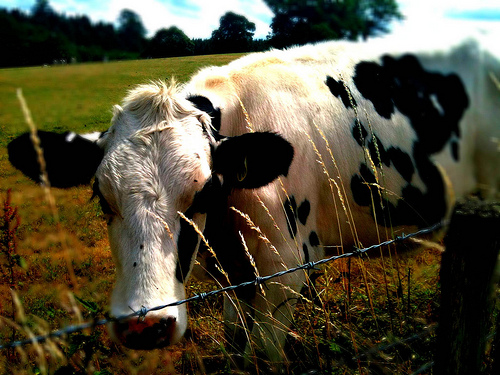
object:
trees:
[204, 11, 255, 54]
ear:
[210, 131, 295, 194]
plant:
[0, 189, 103, 375]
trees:
[0, 6, 31, 70]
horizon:
[0, 49, 233, 72]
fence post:
[437, 184, 496, 373]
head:
[5, 79, 295, 349]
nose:
[121, 314, 170, 347]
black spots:
[319, 52, 472, 229]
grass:
[4, 54, 211, 123]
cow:
[7, 13, 498, 363]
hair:
[116, 73, 199, 127]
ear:
[1, 127, 106, 189]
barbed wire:
[3, 218, 456, 350]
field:
[0, 41, 498, 375]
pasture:
[0, 49, 500, 375]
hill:
[0, 35, 251, 84]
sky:
[0, 0, 500, 41]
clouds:
[394, 0, 499, 22]